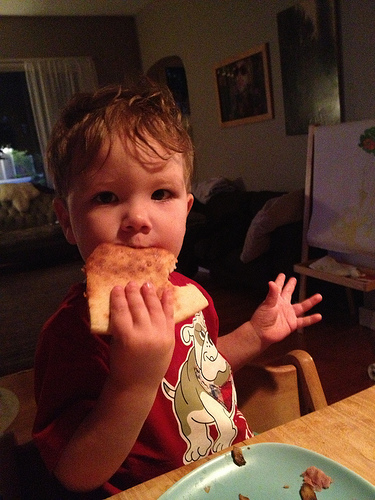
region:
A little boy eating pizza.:
[33, 76, 324, 498]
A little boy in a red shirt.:
[24, 83, 325, 493]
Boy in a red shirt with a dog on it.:
[28, 78, 325, 498]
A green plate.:
[155, 440, 373, 499]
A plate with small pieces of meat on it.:
[154, 439, 374, 499]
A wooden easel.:
[292, 118, 373, 334]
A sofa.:
[0, 182, 66, 267]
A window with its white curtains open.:
[1, 55, 103, 187]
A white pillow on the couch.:
[239, 189, 305, 264]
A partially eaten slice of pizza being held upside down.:
[80, 243, 211, 334]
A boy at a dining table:
[35, 76, 323, 492]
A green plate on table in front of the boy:
[157, 442, 373, 499]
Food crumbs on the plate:
[230, 445, 331, 499]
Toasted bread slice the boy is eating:
[84, 242, 176, 335]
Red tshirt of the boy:
[32, 271, 254, 494]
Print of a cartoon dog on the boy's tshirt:
[160, 311, 236, 465]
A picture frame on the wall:
[210, 43, 273, 126]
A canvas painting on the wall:
[274, 0, 342, 135]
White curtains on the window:
[23, 57, 95, 187]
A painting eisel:
[296, 123, 373, 333]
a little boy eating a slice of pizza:
[34, 75, 325, 494]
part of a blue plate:
[157, 442, 372, 497]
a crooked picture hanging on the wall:
[212, 43, 274, 128]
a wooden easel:
[294, 122, 373, 338]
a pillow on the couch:
[240, 189, 303, 264]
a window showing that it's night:
[0, 61, 47, 187]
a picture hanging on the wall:
[277, 6, 346, 135]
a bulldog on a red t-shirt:
[34, 273, 250, 462]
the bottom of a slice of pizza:
[81, 240, 175, 335]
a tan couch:
[0, 181, 55, 271]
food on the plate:
[300, 467, 330, 491]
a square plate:
[157, 443, 373, 499]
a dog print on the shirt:
[161, 312, 238, 463]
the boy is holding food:
[83, 246, 207, 381]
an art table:
[292, 123, 373, 328]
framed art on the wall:
[207, 42, 273, 128]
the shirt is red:
[34, 274, 239, 497]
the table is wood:
[106, 388, 373, 498]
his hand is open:
[247, 273, 324, 346]